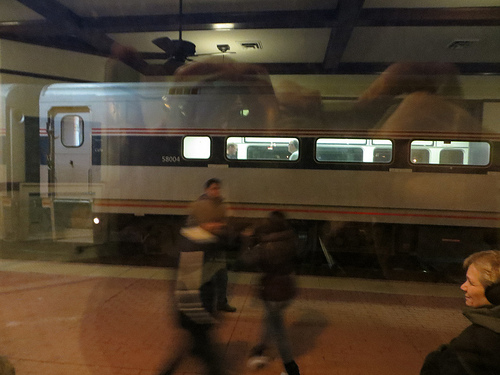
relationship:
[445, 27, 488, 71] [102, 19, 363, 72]
vent in ceiling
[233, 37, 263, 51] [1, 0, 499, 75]
vent in ceiling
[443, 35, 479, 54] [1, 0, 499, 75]
vent in ceiling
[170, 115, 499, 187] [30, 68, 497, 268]
windows of train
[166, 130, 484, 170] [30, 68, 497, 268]
windows on side of train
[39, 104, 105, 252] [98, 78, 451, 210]
door of train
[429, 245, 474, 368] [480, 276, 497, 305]
lady wearing ear muffs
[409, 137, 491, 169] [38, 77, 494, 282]
window on train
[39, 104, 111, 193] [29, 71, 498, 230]
door on train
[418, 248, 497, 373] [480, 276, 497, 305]
woman wearing ear muffs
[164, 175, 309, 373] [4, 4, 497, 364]
people walking at station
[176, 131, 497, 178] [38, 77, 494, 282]
windows on train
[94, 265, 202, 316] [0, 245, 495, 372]
brick on sidewalk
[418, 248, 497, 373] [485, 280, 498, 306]
woman wearing ear muffs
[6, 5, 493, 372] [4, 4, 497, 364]
window at station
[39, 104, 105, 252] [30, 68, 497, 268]
door on train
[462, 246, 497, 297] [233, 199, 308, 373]
hair on people